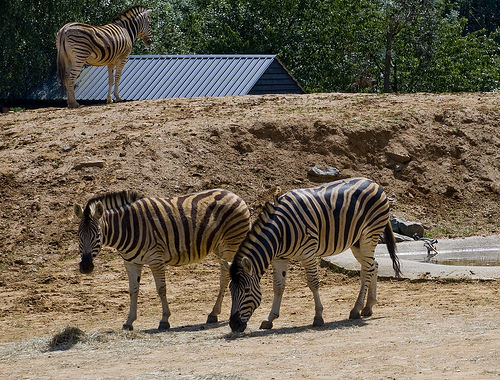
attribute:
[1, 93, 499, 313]
hill — dirt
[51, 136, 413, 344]
zebras — brown , dirty 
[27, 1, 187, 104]
zebras — brown , dirty 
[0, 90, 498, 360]
ground — mud, hilly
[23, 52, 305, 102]
rooftop — iron sheet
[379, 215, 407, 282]
tail — brown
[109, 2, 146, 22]
mane — black, white 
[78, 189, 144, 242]
mane — white , black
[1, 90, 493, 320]
dirt mountain — little, dirt 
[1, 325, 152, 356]
grass — brown , dry 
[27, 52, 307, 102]
roof — blue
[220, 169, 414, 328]
zebra — black, white, looking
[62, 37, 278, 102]
builidng — painted blue, blue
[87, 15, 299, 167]
roof — black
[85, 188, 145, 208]
mane — striped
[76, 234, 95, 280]
muzzle — black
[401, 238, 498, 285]
basin — cement 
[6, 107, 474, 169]
dirt — pile 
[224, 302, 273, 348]
muzzle — black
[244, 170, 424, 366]
zebra — eating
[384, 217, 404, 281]
tail — long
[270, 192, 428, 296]
zebra — covered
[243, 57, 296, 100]
building — wood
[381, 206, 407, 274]
tail — hairy , black 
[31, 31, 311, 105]
roof — blue 